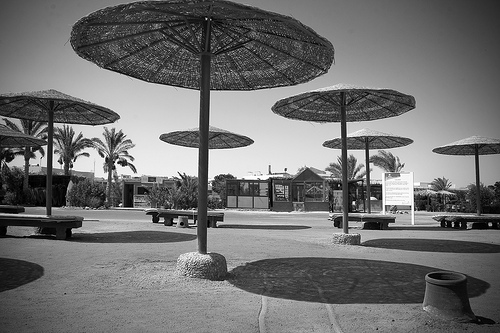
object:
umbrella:
[69, 1, 316, 254]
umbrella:
[0, 117, 48, 151]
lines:
[257, 284, 271, 332]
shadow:
[0, 230, 198, 245]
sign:
[381, 171, 415, 228]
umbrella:
[158, 126, 255, 150]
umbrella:
[271, 81, 415, 232]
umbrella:
[0, 89, 122, 217]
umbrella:
[430, 135, 499, 217]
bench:
[432, 211, 498, 232]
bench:
[150, 208, 225, 228]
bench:
[327, 211, 395, 230]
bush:
[141, 172, 221, 209]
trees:
[66, 178, 116, 213]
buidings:
[272, 167, 350, 212]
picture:
[0, 0, 499, 332]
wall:
[19, 165, 47, 176]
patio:
[0, 167, 498, 333]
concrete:
[0, 208, 499, 332]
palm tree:
[82, 126, 141, 209]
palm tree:
[37, 121, 97, 206]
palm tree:
[0, 114, 59, 206]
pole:
[196, 22, 213, 252]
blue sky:
[0, 1, 499, 186]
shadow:
[226, 257, 489, 304]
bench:
[0, 211, 83, 236]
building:
[2, 166, 96, 206]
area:
[1, 210, 498, 330]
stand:
[175, 251, 233, 282]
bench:
[1, 203, 29, 215]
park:
[0, 0, 498, 330]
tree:
[366, 148, 419, 213]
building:
[118, 177, 178, 208]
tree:
[319, 153, 376, 212]